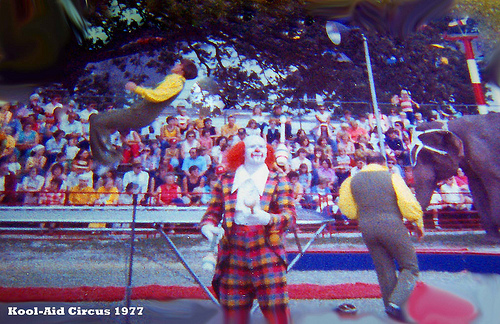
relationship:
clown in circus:
[192, 126, 316, 323] [1, 4, 2, 5]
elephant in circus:
[404, 105, 500, 245] [1, 4, 2, 5]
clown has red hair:
[192, 126, 316, 323] [218, 140, 280, 172]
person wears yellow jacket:
[66, 173, 97, 208] [65, 185, 99, 209]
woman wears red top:
[148, 173, 188, 204] [154, 183, 179, 205]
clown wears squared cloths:
[192, 126, 316, 323] [198, 168, 301, 323]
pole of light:
[354, 29, 394, 158] [320, 14, 357, 47]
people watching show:
[0, 90, 473, 214] [76, 44, 499, 319]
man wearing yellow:
[66, 173, 97, 208] [65, 185, 99, 209]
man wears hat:
[65, 158, 95, 183] [71, 158, 92, 172]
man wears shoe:
[326, 145, 432, 323] [373, 299, 419, 324]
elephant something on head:
[404, 105, 500, 245] [399, 116, 466, 194]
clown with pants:
[192, 126, 316, 323] [215, 222, 295, 324]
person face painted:
[192, 126, 316, 323] [240, 129, 269, 166]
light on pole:
[320, 14, 357, 47] [354, 29, 394, 158]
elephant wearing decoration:
[404, 105, 500, 245] [399, 125, 448, 168]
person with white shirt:
[117, 158, 153, 190] [119, 173, 154, 194]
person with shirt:
[33, 175, 70, 211] [35, 187, 70, 206]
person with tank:
[148, 173, 188, 204] [154, 183, 179, 205]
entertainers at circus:
[78, 54, 441, 324] [1, 4, 2, 5]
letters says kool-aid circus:
[4, 301, 151, 321] [7, 305, 114, 324]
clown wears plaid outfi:
[192, 126, 316, 323] [198, 168, 301, 323]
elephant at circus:
[404, 105, 500, 245] [1, 4, 2, 5]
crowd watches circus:
[0, 90, 473, 214] [1, 4, 2, 5]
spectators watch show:
[0, 90, 473, 214] [76, 44, 499, 319]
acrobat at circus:
[75, 46, 204, 174] [1, 4, 2, 5]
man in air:
[75, 46, 204, 174] [2, 3, 482, 200]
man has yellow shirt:
[326, 145, 432, 323] [328, 161, 431, 229]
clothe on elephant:
[399, 125, 448, 168] [404, 105, 500, 245]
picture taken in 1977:
[3, 3, 494, 323] [113, 302, 150, 322]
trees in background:
[67, 3, 484, 91] [0, 1, 499, 94]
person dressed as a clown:
[192, 126, 316, 323] [192, 126, 316, 323]